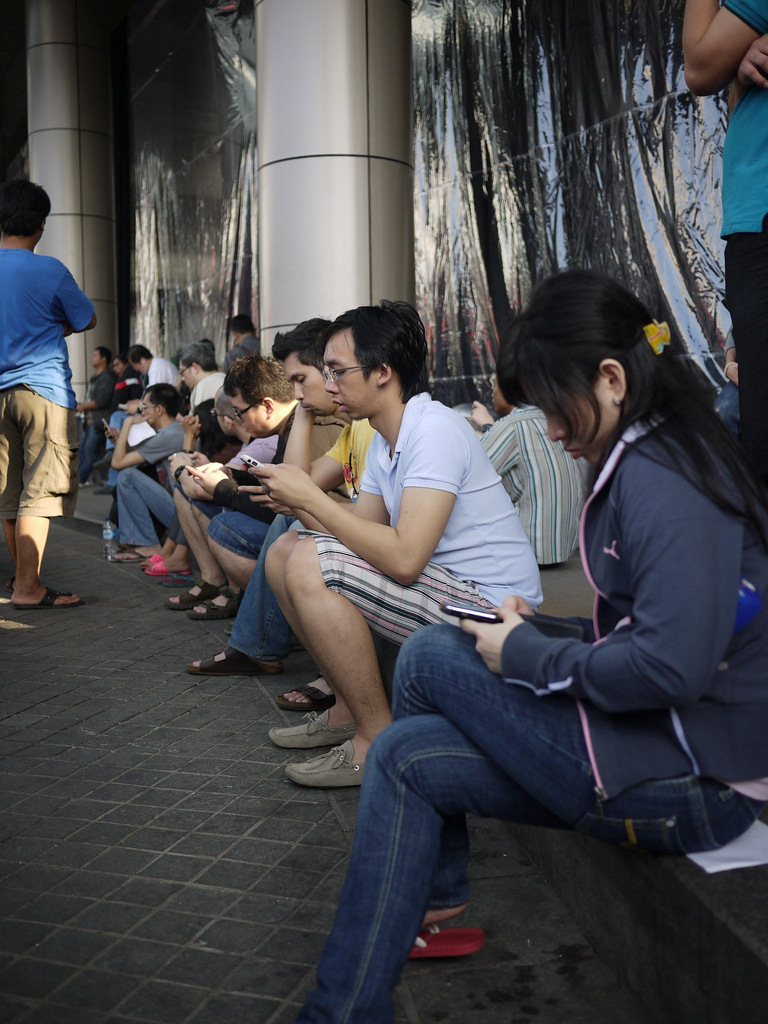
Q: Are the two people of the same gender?
A: No, they are both male and female.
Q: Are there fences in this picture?
A: No, there are no fences.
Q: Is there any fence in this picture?
A: No, there are no fences.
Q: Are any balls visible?
A: No, there are no balls.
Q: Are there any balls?
A: No, there are no balls.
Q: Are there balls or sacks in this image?
A: No, there are no balls or sacks.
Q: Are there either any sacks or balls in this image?
A: No, there are no balls or sacks.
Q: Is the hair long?
A: Yes, the hair is long.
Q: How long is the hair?
A: The hair is long.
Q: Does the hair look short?
A: No, the hair is long.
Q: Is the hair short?
A: No, the hair is long.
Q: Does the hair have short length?
A: No, the hair is long.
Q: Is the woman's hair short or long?
A: The hair is long.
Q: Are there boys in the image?
A: No, there are no boys.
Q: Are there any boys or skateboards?
A: No, there are no boys or skateboards.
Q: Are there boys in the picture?
A: No, there are no boys.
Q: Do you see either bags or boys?
A: No, there are no boys or bags.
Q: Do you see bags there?
A: No, there are no bags.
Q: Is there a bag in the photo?
A: No, there are no bags.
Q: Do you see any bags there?
A: No, there are no bags.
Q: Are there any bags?
A: No, there are no bags.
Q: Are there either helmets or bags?
A: No, there are no bags or helmets.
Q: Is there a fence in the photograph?
A: No, there are no fences.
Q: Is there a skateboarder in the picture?
A: No, there are no skateboarders.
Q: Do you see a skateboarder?
A: No, there are no skateboarders.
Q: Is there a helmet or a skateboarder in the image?
A: No, there are no skateboarders or helmets.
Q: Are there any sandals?
A: Yes, there are sandals.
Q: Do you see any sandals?
A: Yes, there are sandals.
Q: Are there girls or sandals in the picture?
A: Yes, there are sandals.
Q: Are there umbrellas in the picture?
A: No, there are no umbrellas.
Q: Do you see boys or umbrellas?
A: No, there are no umbrellas or boys.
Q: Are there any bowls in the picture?
A: No, there are no bowls.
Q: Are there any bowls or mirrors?
A: No, there are no bowls or mirrors.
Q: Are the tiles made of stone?
A: Yes, the tiles are made of stone.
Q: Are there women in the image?
A: Yes, there is a woman.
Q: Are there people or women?
A: Yes, there is a woman.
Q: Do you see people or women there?
A: Yes, there is a woman.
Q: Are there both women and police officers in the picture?
A: No, there is a woman but no policemen.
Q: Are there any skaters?
A: No, there are no skaters.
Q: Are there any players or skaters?
A: No, there are no skaters or players.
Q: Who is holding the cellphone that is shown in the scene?
A: The woman is holding the cellphone.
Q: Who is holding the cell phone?
A: The woman is holding the cellphone.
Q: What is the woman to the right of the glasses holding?
A: The woman is holding the mobile phone.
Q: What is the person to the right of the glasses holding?
A: The woman is holding the mobile phone.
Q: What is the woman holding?
A: The woman is holding the mobile phone.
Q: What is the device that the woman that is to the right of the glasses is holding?
A: The device is a cell phone.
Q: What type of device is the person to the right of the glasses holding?
A: The woman is holding the mobile phone.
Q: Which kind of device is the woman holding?
A: The woman is holding the mobile phone.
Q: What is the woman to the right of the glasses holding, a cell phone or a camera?
A: The woman is holding a cell phone.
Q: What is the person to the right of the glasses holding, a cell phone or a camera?
A: The woman is holding a cell phone.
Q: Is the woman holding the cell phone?
A: Yes, the woman is holding the cell phone.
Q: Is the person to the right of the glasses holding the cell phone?
A: Yes, the woman is holding the cell phone.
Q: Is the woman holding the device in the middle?
A: Yes, the woman is holding the cell phone.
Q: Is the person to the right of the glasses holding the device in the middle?
A: Yes, the woman is holding the cell phone.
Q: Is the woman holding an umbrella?
A: No, the woman is holding the cell phone.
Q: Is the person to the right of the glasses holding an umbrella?
A: No, the woman is holding the cell phone.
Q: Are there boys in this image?
A: No, there are no boys.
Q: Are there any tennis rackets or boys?
A: No, there are no boys or tennis rackets.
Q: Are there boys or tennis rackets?
A: No, there are no boys or tennis rackets.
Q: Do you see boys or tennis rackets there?
A: No, there are no boys or tennis rackets.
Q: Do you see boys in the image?
A: No, there are no boys.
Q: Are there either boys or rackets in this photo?
A: No, there are no boys or rackets.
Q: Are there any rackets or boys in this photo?
A: No, there are no boys or rackets.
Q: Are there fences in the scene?
A: No, there are no fences.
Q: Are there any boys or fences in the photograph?
A: No, there are no fences or boys.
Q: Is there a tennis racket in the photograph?
A: No, there are no rackets.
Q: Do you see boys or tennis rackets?
A: No, there are no tennis rackets or boys.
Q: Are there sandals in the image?
A: Yes, there are sandals.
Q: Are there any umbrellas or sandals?
A: Yes, there are sandals.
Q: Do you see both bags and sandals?
A: No, there are sandals but no bags.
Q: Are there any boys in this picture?
A: No, there are no boys.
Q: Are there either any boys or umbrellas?
A: No, there are no boys or umbrellas.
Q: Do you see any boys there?
A: No, there are no boys.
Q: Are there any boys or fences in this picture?
A: No, there are no boys or fences.